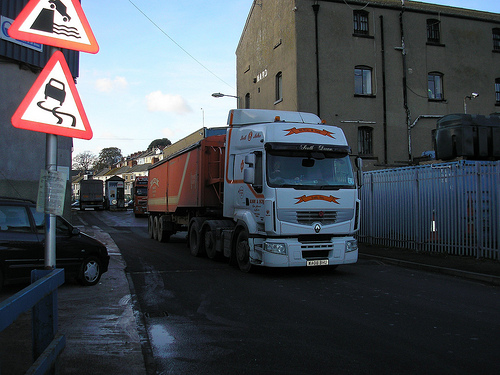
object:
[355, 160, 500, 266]
fence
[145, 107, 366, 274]
truck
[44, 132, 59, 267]
post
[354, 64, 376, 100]
window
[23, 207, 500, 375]
street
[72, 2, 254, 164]
sky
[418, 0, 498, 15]
sky